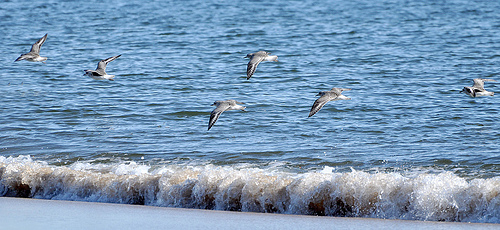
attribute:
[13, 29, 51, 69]
bird — grey, black, white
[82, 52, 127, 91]
bird — grey, black, white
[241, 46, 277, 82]
bird — grey, black, white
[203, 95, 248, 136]
bird — grey, black, white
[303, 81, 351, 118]
bird — grey, black, white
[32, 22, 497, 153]
birds — gains speed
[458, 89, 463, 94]
beak — sharp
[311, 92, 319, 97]
beak — sharp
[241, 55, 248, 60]
beak — sharp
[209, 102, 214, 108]
beak — sharp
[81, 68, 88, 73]
beak — sharp